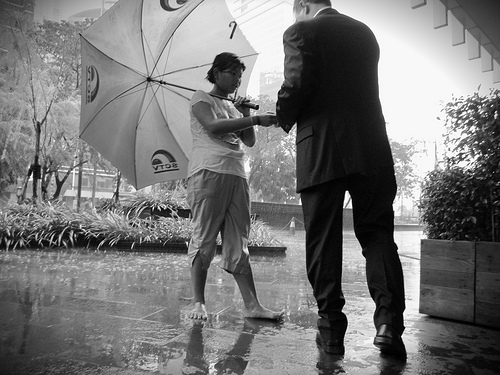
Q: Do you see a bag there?
A: No, there are no bags.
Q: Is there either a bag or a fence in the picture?
A: No, there are no bags or fences.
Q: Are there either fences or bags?
A: No, there are no bags or fences.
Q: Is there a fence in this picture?
A: No, there are no fences.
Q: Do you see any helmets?
A: No, there are no helmets.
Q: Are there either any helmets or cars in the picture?
A: No, there are no helmets or cars.